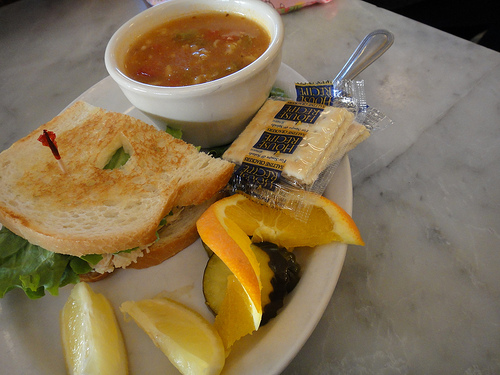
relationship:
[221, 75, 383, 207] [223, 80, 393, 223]
crackers wrapped in plastic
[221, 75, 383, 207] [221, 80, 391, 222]
crackers in packets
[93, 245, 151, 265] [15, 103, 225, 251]
tuna in bread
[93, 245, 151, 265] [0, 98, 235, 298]
tuna in sandwich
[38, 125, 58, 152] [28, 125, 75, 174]
plastic curls on toothpick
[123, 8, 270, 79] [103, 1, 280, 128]
soup in bowl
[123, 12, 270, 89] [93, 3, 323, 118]
soup in bowl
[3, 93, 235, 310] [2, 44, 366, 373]
food on plate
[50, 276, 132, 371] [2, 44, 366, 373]
food on plate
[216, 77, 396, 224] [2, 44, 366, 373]
crackers on plate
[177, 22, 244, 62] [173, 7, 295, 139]
soup inside white bowl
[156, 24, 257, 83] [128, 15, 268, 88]
vegetables are inside soup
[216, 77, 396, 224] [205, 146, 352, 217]
crackers are inside wrap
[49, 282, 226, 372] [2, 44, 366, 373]
lemon are on plate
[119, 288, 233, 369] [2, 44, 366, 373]
lemon on a plate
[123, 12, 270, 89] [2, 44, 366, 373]
soup are lunch on a plate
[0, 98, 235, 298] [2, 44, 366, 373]
sandwich are lunch on a plate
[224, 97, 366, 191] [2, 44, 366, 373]
cracker are on plate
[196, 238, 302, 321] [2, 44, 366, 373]
pickles are on plate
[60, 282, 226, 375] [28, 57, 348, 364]
lemon are on plate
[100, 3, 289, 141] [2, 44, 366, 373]
cup on plate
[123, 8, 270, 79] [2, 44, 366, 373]
soup on plate